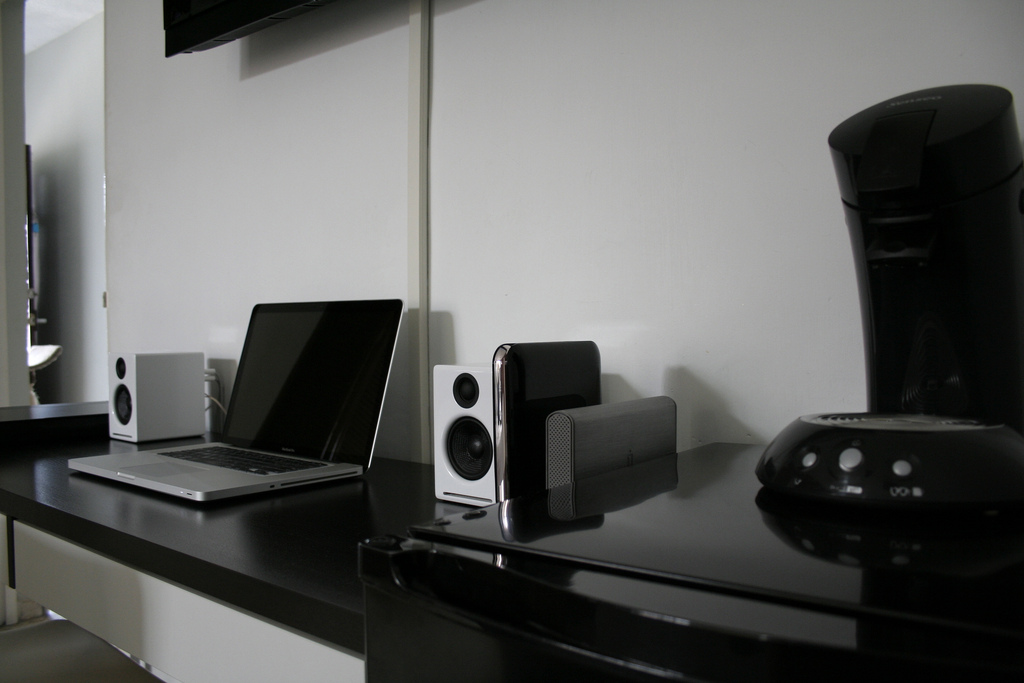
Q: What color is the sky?
A: Blue.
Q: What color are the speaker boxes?
A: White.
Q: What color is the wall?
A: White.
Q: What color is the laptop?
A: Silver.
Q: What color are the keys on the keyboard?
A: Black.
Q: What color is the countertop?
A: Black.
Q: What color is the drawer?
A: White.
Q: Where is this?
A: A home office.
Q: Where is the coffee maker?
A: On top of the mini fridge.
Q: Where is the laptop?
A: On the desk.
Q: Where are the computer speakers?
A: On either side of the laptop.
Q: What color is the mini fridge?
A: It is black.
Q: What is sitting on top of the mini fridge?
A: A coffee maker.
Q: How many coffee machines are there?
A: 1.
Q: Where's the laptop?
A: Sitting on the desk.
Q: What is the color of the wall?
A: White.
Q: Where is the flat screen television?
A: Hanging on the wall above the desk.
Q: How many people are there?
A: None.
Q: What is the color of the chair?
A: There isn't one.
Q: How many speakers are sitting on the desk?
A: 2.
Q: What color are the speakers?
A: Silver with black.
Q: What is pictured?
A: A workstation.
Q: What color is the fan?
A: Black.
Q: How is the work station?
A: Clean and tidy.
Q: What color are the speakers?
A: White.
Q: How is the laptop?
A: Open and off.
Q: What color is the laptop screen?
A: Black.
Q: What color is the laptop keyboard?
A: Black.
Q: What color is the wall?
A: White.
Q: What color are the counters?
A: Black.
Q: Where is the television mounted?
A: Above the laptop.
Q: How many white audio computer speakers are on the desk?
A: Two.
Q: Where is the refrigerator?
A: Bottom right hand side of the photo.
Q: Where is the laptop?
A: Between the speakers.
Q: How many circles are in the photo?
A: Eight.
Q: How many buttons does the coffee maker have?
A: Three.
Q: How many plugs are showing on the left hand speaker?
A: Three.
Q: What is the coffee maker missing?
A: Coffee pot.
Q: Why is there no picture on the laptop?
A: Laptop is off.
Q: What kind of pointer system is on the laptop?
A: Finger pad.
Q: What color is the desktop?
A: Black.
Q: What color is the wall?
A: White.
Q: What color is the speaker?
A: White.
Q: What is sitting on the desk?
A: A laptop.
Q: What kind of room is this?
A: A computer room.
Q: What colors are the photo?
A: Black and white.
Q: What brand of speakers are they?
A: Bose.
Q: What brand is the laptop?
A: Acer.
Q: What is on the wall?
A: A television.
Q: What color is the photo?
A: Black and white.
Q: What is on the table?
A: Laptop.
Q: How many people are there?
A: None.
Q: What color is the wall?
A: White.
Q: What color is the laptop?
A: Silver.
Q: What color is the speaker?
A: White and black.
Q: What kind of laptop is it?
A: Apple.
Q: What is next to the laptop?
A: Speakers.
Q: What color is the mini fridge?
A: Black.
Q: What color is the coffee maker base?
A: Black.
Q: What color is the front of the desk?
A: White.